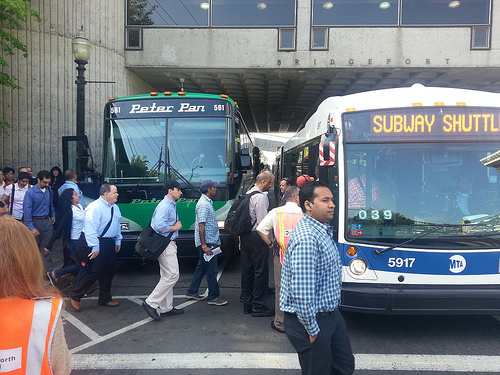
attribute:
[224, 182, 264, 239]
backpack — black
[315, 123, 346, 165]
mirror — black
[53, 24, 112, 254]
lampost — tall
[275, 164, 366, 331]
shirt — checkered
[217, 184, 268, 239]
bookbag — black, book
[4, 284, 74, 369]
vest — orange, silver, workers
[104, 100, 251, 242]
bus — large, green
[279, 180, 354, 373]
man — checkered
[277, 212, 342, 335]
shirt — blue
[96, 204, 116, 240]
strap — shoulder